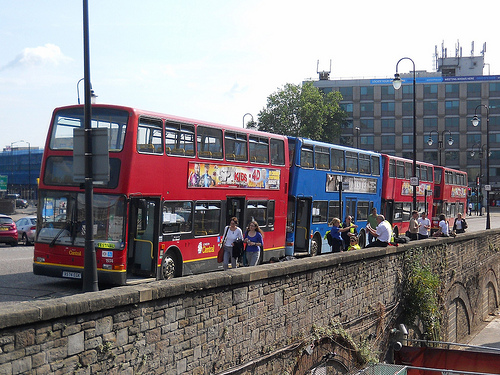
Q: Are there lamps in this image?
A: Yes, there is a lamp.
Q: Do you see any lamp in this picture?
A: Yes, there is a lamp.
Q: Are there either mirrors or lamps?
A: Yes, there is a lamp.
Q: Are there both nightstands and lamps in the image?
A: No, there is a lamp but no nightstands.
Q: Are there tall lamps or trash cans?
A: Yes, there is a tall lamp.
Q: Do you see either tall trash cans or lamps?
A: Yes, there is a tall lamp.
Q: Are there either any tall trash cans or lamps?
A: Yes, there is a tall lamp.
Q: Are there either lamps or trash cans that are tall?
A: Yes, the lamp is tall.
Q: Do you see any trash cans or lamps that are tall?
A: Yes, the lamp is tall.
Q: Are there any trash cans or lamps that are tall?
A: Yes, the lamp is tall.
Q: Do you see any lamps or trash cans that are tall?
A: Yes, the lamp is tall.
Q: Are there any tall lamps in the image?
A: Yes, there is a tall lamp.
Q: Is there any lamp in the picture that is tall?
A: Yes, there is a lamp that is tall.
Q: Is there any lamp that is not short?
A: Yes, there is a tall lamp.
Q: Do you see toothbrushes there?
A: No, there are no toothbrushes.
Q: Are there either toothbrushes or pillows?
A: No, there are no toothbrushes or pillows.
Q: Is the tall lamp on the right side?
A: Yes, the lamp is on the right of the image.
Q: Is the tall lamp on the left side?
A: No, the lamp is on the right of the image.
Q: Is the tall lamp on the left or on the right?
A: The lamp is on the right of the image.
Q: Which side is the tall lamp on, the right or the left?
A: The lamp is on the right of the image.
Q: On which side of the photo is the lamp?
A: The lamp is on the right of the image.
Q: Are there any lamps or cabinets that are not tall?
A: No, there is a lamp but it is tall.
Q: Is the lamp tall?
A: Yes, the lamp is tall.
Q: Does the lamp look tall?
A: Yes, the lamp is tall.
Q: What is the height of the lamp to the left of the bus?
A: The lamp is tall.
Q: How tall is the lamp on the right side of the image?
A: The lamp is tall.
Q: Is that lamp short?
A: No, the lamp is tall.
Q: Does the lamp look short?
A: No, the lamp is tall.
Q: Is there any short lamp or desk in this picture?
A: No, there is a lamp but it is tall.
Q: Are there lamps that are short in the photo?
A: No, there is a lamp but it is tall.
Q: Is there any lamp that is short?
A: No, there is a lamp but it is tall.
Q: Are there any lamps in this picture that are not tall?
A: No, there is a lamp but it is tall.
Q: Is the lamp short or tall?
A: The lamp is tall.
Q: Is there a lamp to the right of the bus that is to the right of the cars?
A: Yes, there is a lamp to the right of the bus.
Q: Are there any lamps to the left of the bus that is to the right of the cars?
A: No, the lamp is to the right of the bus.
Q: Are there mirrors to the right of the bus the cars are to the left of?
A: No, there is a lamp to the right of the bus.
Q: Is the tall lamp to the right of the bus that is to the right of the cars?
A: Yes, the lamp is to the right of the bus.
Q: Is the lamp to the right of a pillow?
A: No, the lamp is to the right of the bus.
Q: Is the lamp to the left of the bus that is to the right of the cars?
A: No, the lamp is to the right of the bus.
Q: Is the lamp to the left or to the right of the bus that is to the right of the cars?
A: The lamp is to the right of the bus.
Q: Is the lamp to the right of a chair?
A: No, the lamp is to the right of the bus.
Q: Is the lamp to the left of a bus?
A: Yes, the lamp is to the left of a bus.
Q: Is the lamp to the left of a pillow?
A: No, the lamp is to the left of a bus.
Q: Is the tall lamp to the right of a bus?
A: No, the lamp is to the left of a bus.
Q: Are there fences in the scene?
A: No, there are no fences.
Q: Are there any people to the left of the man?
A: Yes, there are people to the left of the man.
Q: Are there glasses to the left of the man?
A: No, there are people to the left of the man.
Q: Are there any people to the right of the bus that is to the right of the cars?
A: Yes, there are people to the right of the bus.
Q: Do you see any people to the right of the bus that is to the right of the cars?
A: Yes, there are people to the right of the bus.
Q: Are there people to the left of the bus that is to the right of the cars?
A: No, the people are to the right of the bus.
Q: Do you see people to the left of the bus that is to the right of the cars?
A: No, the people are to the right of the bus.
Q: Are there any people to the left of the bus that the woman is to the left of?
A: No, the people are to the right of the bus.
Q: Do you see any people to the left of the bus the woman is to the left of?
A: No, the people are to the right of the bus.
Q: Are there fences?
A: No, there are no fences.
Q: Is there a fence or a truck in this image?
A: No, there are no fences or trucks.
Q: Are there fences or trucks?
A: No, there are no fences or trucks.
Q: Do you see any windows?
A: Yes, there is a window.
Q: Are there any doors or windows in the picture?
A: Yes, there is a window.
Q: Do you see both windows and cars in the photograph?
A: Yes, there are both a window and a car.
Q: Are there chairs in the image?
A: No, there are no chairs.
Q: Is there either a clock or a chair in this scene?
A: No, there are no chairs or clocks.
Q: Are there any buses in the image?
A: Yes, there is a bus.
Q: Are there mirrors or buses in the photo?
A: Yes, there is a bus.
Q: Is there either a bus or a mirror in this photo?
A: Yes, there is a bus.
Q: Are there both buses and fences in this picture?
A: No, there is a bus but no fences.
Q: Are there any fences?
A: No, there are no fences.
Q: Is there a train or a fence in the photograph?
A: No, there are no fences or trains.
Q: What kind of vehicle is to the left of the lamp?
A: The vehicle is a bus.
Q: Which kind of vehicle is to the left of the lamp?
A: The vehicle is a bus.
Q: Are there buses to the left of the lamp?
A: Yes, there is a bus to the left of the lamp.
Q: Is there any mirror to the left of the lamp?
A: No, there is a bus to the left of the lamp.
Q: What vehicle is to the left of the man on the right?
A: The vehicle is a bus.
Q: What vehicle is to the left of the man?
A: The vehicle is a bus.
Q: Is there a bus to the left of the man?
A: Yes, there is a bus to the left of the man.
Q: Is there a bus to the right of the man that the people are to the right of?
A: No, the bus is to the left of the man.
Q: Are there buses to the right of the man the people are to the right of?
A: No, the bus is to the left of the man.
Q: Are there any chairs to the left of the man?
A: No, there is a bus to the left of the man.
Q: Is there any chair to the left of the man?
A: No, there is a bus to the left of the man.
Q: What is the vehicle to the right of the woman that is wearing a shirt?
A: The vehicle is a bus.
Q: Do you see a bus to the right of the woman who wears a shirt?
A: Yes, there is a bus to the right of the woman.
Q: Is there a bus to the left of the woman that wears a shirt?
A: No, the bus is to the right of the woman.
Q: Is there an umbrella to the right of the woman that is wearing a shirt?
A: No, there is a bus to the right of the woman.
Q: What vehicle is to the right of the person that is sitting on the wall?
A: The vehicle is a bus.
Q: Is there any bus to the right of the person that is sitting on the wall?
A: Yes, there is a bus to the right of the person.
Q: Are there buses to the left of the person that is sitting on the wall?
A: No, the bus is to the right of the person.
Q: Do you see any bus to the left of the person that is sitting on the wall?
A: No, the bus is to the right of the person.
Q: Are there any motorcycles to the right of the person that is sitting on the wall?
A: No, there is a bus to the right of the person.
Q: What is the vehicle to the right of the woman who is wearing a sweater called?
A: The vehicle is a bus.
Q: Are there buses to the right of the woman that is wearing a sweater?
A: Yes, there is a bus to the right of the woman.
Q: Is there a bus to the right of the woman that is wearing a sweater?
A: Yes, there is a bus to the right of the woman.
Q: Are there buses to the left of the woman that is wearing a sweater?
A: No, the bus is to the right of the woman.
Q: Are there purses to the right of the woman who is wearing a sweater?
A: No, there is a bus to the right of the woman.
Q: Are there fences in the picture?
A: No, there are no fences.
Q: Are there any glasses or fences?
A: No, there are no fences or glasses.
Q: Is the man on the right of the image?
A: Yes, the man is on the right of the image.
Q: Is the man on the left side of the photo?
A: No, the man is on the right of the image.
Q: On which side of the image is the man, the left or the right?
A: The man is on the right of the image.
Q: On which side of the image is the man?
A: The man is on the right of the image.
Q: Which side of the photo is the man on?
A: The man is on the right of the image.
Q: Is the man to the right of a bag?
A: No, the man is to the right of a person.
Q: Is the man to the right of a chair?
A: No, the man is to the right of the bus.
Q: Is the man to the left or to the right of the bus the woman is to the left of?
A: The man is to the right of the bus.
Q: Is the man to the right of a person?
A: Yes, the man is to the right of a person.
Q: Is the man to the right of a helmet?
A: No, the man is to the right of a person.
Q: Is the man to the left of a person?
A: No, the man is to the right of a person.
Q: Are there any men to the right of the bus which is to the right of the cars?
A: Yes, there is a man to the right of the bus.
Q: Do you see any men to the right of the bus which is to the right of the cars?
A: Yes, there is a man to the right of the bus.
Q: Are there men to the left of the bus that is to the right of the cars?
A: No, the man is to the right of the bus.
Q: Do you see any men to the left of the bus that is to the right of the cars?
A: No, the man is to the right of the bus.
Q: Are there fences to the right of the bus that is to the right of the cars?
A: No, there is a man to the right of the bus.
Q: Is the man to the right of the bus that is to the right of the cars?
A: Yes, the man is to the right of the bus.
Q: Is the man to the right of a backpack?
A: No, the man is to the right of the bus.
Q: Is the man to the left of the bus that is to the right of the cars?
A: No, the man is to the right of the bus.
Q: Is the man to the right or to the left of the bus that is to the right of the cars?
A: The man is to the right of the bus.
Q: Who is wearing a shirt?
A: The man is wearing a shirt.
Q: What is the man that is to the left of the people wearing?
A: The man is wearing a shirt.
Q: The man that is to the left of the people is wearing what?
A: The man is wearing a shirt.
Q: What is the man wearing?
A: The man is wearing a shirt.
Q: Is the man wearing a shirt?
A: Yes, the man is wearing a shirt.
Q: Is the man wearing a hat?
A: No, the man is wearing a shirt.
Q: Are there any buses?
A: Yes, there is a bus.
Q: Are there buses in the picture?
A: Yes, there is a bus.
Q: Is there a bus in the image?
A: Yes, there is a bus.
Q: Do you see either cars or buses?
A: Yes, there is a bus.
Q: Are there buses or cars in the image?
A: Yes, there is a bus.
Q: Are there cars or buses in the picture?
A: Yes, there is a bus.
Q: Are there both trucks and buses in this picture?
A: No, there is a bus but no trucks.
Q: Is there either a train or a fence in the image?
A: No, there are no trains or fences.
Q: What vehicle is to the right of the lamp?
A: The vehicle is a bus.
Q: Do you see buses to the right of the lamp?
A: Yes, there is a bus to the right of the lamp.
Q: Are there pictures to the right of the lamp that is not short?
A: No, there is a bus to the right of the lamp.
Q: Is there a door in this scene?
A: Yes, there is a door.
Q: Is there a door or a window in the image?
A: Yes, there is a door.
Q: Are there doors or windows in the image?
A: Yes, there is a door.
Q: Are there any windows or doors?
A: Yes, there is a door.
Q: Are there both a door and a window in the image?
A: Yes, there are both a door and a window.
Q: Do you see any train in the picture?
A: No, there are no trains.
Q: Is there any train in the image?
A: No, there are no trains.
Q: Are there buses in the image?
A: Yes, there is a bus.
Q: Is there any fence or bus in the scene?
A: Yes, there is a bus.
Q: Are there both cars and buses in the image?
A: Yes, there are both a bus and a car.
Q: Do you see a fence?
A: No, there are no fences.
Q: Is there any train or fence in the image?
A: No, there are no fences or trains.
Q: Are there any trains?
A: No, there are no trains.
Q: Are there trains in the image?
A: No, there are no trains.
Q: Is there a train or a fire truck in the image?
A: No, there are no trains or fire trucks.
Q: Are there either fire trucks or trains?
A: No, there are no trains or fire trucks.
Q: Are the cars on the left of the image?
A: Yes, the cars are on the left of the image.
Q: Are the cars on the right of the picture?
A: No, the cars are on the left of the image.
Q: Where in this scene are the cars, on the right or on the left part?
A: The cars are on the left of the image.